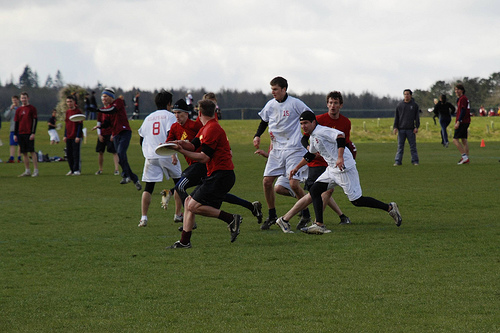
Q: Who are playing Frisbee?
A: The men.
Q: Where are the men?
A: On the field.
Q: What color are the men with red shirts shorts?
A: Black.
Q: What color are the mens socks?
A: Black and white.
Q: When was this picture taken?
A: During the day.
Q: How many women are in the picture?
A: None.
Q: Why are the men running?
A: They are playing.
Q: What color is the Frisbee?
A: White.